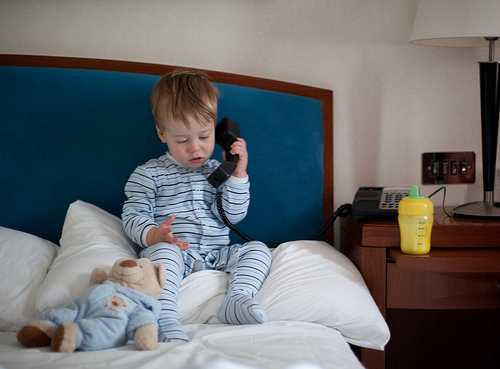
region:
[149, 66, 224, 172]
the head of a boy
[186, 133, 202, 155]
the nose of a boy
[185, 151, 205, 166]
the mouth of a boy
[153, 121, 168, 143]
the ear of a boy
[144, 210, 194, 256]
the hand of a boy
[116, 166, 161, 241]
the arm of a boy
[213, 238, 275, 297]
the leg of a boy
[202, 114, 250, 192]
a black telephone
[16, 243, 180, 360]
a tan teddy bear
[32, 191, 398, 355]
a white pillow on the bed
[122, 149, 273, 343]
blue and white stripped outfit on baby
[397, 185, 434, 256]
a yellow sippy cup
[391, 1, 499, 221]
a tall lamp on table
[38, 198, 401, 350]
a long, white pillow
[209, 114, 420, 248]
a black telephone with cord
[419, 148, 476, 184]
a silver light fixture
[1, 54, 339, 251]
a wooden headrest with blue cloth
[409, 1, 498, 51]
a white lamp shade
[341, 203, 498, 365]
a wooden side table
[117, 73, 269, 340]
toddler holding phone receiver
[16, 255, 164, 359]
teddy bear in blue pajamas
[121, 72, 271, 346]
toddler in striped pajamas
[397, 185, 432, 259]
a yellow plastic object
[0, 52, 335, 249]
a headboard of blue and brown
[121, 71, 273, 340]
toddler sitting on a pillow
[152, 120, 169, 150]
right ear of the toddler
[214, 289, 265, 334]
left foot of the toddler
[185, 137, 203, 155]
nose of the toddler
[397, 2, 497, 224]
a lamp sitting on furniture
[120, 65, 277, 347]
the toddler is a boy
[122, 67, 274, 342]
a toddler holding a telephone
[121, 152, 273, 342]
blue striped pajamas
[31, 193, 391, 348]
the pillow is white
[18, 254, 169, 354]
the teddy bear is wearing blue pajamas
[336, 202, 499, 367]
a wooden night stand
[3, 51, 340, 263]
the headboard is blue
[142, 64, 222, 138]
brown hair on the toddler boy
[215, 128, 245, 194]
the phone is black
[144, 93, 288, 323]
the baby has striped clothes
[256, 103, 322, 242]
the cushion is blue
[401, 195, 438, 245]
the plastic is yellow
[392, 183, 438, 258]
there is milk in the conatiner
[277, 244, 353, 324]
the pillow is white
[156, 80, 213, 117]
the hair is brown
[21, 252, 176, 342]
the teddy bear is brown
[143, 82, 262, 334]
the baby is talking on the phone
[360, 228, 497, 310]
the drawer is wooden